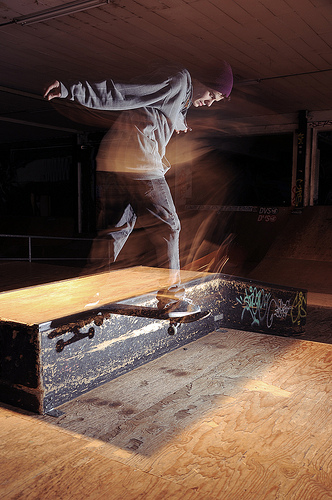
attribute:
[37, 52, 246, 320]
boy — standing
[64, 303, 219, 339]
skateboard — here, black, hanging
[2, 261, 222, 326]
ramp — unpainted, wooden, chipped, painted, black, skateboard's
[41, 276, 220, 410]
side — painted, ramp's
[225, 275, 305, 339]
side — painted, ramp's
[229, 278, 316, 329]
graffiti — white, blue, yellow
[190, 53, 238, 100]
beanie — purple, violet, knit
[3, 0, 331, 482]
image — boy, blurred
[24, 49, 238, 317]
man — focusing, intently focusing, here, light skinned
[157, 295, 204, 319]
shoe — see through, black, white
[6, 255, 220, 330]
deck — wooden, light, brown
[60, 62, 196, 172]
sweater — grey, hoodie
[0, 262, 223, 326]
beam — floor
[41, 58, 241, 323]
skateboarder — ghostly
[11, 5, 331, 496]
exposure — translucent, double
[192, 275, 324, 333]
portion — slanted, ramp's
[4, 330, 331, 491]
floor — worn, wood, here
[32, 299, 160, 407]
end — ramp's, flat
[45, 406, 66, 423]
bracket — old looking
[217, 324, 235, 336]
bracket — old looking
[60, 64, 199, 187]
hoodie — grey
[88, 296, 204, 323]
shoes — black, white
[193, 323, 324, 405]
shadow — light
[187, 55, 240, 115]
head — man's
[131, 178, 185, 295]
leg — man's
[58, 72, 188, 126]
arm — man's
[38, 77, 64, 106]
hand — man's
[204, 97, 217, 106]
nose — man's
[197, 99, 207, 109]
mouth — man's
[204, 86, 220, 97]
eye — man's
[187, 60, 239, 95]
cap — purple, stocking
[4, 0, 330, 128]
roof — here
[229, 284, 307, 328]
writing — here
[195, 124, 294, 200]
door — opened, here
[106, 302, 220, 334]
board — here, brown